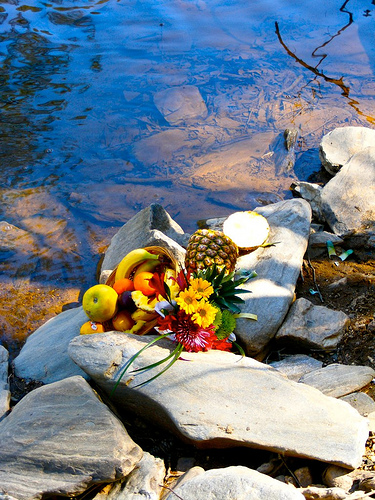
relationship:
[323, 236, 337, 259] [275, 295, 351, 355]
debris next to rock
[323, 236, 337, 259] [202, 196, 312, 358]
debris next to rock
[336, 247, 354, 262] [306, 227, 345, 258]
debris next to rock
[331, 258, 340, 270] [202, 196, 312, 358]
debris next to rock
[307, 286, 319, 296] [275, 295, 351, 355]
debris next to rock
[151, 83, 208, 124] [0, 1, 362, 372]
rocks under water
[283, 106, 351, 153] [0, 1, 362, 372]
rocks under water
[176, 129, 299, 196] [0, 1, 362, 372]
rocks under water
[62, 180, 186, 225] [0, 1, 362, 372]
rocks under water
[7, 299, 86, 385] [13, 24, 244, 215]
rock next to water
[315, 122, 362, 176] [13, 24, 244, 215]
rock next to water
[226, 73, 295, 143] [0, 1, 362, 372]
sticks in water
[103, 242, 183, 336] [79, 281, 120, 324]
basket has fruit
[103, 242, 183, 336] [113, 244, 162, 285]
basket has fruit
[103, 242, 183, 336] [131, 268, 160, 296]
basket has fruit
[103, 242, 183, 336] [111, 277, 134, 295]
basket has fruit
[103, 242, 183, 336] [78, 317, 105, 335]
basket has fruit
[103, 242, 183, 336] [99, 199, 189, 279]
basket on rock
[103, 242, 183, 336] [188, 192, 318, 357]
basket on rock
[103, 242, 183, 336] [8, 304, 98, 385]
basket on rock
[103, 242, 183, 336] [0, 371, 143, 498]
basket on rock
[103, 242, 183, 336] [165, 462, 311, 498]
basket on rock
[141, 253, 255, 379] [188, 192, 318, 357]
flowers on rock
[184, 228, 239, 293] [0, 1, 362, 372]
pineapple next to water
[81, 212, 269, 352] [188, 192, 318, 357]
fruit next to rock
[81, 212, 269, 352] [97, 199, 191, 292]
fruit next to rock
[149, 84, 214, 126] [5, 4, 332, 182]
rock in water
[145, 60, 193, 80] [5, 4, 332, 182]
rock in water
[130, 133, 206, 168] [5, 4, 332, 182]
rock in water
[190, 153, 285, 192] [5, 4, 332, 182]
rock in water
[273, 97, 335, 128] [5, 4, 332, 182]
rock in water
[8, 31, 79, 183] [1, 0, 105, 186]
tree in reflection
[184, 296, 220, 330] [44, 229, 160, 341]
flower with fruit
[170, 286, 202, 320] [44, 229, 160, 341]
flower with fruit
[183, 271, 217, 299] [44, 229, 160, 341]
flower with fruit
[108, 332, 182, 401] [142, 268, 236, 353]
foliage with flowers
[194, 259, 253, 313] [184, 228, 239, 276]
fronds on pineapple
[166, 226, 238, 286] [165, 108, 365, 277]
pineapple on rocks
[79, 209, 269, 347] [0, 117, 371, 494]
fruit on rocks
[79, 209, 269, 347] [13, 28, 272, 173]
fruit next to water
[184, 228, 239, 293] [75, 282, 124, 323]
pineapple next to fruit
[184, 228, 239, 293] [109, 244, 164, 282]
pineapple next to fruit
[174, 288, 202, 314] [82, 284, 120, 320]
flower next to fruit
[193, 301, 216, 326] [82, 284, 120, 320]
flower next to fruit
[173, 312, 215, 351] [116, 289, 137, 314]
flower next to fruit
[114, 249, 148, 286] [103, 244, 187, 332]
banana in basket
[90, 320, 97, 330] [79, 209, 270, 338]
sticker on fruit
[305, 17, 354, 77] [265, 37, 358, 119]
reflection in water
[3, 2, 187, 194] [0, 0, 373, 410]
ripple in water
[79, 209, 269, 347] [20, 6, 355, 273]
fruit next to water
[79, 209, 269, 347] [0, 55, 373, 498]
fruit on rocks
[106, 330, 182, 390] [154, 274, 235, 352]
foliage on bouqet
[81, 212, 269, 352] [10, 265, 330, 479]
fruit on rocks